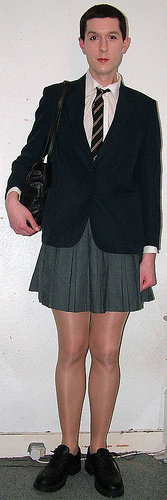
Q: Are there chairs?
A: No, there are no chairs.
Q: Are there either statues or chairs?
A: No, there are no chairs or statues.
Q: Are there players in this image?
A: No, there are no players.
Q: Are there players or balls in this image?
A: No, there are no players or balls.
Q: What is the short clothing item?
A: The clothing item is a skirt.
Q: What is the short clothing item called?
A: The clothing item is a skirt.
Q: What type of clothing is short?
A: The clothing is a skirt.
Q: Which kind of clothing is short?
A: The clothing is a skirt.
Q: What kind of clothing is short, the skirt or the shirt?
A: The skirt is short.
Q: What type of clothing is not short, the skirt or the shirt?
A: The shirt is not short.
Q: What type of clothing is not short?
A: The clothing is a shirt.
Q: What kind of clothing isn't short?
A: The clothing is a shirt.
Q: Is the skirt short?
A: Yes, the skirt is short.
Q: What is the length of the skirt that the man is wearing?
A: The skirt is short.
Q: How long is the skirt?
A: The skirt is short.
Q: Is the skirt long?
A: No, the skirt is short.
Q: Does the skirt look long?
A: No, the skirt is short.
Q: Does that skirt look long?
A: No, the skirt is short.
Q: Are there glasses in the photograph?
A: No, there are no glasses.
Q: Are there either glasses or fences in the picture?
A: No, there are no glasses or fences.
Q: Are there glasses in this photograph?
A: No, there are no glasses.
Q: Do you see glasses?
A: No, there are no glasses.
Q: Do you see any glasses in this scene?
A: No, there are no glasses.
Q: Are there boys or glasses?
A: No, there are no glasses or boys.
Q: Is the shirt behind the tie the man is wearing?
A: Yes, the shirt is behind the tie.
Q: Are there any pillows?
A: No, there are no pillows.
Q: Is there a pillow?
A: No, there are no pillows.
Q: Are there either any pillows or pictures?
A: No, there are no pillows or pictures.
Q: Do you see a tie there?
A: Yes, there is a tie.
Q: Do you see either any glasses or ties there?
A: Yes, there is a tie.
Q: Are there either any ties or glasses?
A: Yes, there is a tie.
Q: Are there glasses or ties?
A: Yes, there is a tie.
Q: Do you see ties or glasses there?
A: Yes, there is a tie.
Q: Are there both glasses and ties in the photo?
A: No, there is a tie but no glasses.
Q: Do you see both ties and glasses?
A: No, there is a tie but no glasses.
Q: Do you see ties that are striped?
A: Yes, there is a striped tie.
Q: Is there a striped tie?
A: Yes, there is a striped tie.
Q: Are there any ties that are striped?
A: Yes, there is a tie that is striped.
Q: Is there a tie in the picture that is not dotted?
A: Yes, there is a striped tie.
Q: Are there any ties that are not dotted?
A: Yes, there is a striped tie.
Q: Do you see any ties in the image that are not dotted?
A: Yes, there is a striped tie.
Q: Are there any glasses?
A: No, there are no glasses.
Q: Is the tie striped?
A: Yes, the tie is striped.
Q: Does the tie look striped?
A: Yes, the tie is striped.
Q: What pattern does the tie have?
A: The tie has striped pattern.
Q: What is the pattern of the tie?
A: The tie is striped.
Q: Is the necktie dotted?
A: No, the necktie is striped.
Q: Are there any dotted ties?
A: No, there is a tie but it is striped.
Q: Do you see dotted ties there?
A: No, there is a tie but it is striped.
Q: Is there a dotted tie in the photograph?
A: No, there is a tie but it is striped.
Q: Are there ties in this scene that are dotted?
A: No, there is a tie but it is striped.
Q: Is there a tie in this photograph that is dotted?
A: No, there is a tie but it is striped.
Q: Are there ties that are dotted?
A: No, there is a tie but it is striped.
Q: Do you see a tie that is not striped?
A: No, there is a tie but it is striped.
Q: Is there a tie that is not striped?
A: No, there is a tie but it is striped.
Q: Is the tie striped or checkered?
A: The tie is striped.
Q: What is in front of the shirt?
A: The tie is in front of the shirt.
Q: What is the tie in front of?
A: The tie is in front of the shirt.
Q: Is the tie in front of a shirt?
A: Yes, the tie is in front of a shirt.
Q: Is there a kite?
A: No, there are no kites.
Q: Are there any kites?
A: No, there are no kites.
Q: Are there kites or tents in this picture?
A: No, there are no kites or tents.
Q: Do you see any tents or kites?
A: No, there are no kites or tents.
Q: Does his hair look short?
A: Yes, the hair is short.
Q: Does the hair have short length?
A: Yes, the hair is short.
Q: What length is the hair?
A: The hair is short.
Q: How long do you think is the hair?
A: The hair is short.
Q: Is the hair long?
A: No, the hair is short.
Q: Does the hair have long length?
A: No, the hair is short.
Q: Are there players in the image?
A: No, there are no players.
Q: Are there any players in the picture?
A: No, there are no players.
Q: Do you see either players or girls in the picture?
A: No, there are no players or girls.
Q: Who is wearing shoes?
A: The man is wearing shoes.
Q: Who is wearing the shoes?
A: The man is wearing shoes.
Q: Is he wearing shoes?
A: Yes, the man is wearing shoes.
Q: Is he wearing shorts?
A: No, the man is wearing shoes.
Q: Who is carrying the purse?
A: The man is carrying the purse.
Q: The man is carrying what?
A: The man is carrying a purse.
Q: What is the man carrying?
A: The man is carrying a purse.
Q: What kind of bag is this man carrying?
A: The man is carrying a purse.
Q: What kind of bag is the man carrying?
A: The man is carrying a purse.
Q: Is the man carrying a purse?
A: Yes, the man is carrying a purse.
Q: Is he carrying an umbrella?
A: No, the man is carrying a purse.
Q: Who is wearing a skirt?
A: The man is wearing a skirt.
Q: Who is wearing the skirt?
A: The man is wearing a skirt.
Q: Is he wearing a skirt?
A: Yes, the man is wearing a skirt.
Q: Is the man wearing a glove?
A: No, the man is wearing a skirt.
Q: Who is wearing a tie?
A: The man is wearing a tie.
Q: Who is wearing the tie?
A: The man is wearing a tie.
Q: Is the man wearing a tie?
A: Yes, the man is wearing a tie.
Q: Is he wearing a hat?
A: No, the man is wearing a tie.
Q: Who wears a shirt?
A: The man wears a shirt.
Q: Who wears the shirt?
A: The man wears a shirt.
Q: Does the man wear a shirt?
A: Yes, the man wears a shirt.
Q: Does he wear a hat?
A: No, the man wears a shirt.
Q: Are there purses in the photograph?
A: Yes, there is a purse.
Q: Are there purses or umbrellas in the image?
A: Yes, there is a purse.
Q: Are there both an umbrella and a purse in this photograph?
A: No, there is a purse but no umbrellas.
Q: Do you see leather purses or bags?
A: Yes, there is a leather purse.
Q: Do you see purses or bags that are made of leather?
A: Yes, the purse is made of leather.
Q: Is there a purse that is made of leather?
A: Yes, there is a purse that is made of leather.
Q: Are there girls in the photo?
A: No, there are no girls.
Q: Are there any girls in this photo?
A: No, there are no girls.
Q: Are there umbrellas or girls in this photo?
A: No, there are no girls or umbrellas.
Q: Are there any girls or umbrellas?
A: No, there are no girls or umbrellas.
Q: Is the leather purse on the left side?
A: Yes, the purse is on the left of the image.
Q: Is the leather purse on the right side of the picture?
A: No, the purse is on the left of the image.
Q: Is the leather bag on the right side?
A: No, the purse is on the left of the image.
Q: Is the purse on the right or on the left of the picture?
A: The purse is on the left of the image.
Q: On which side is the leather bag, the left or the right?
A: The purse is on the left of the image.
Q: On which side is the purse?
A: The purse is on the left of the image.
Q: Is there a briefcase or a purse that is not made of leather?
A: No, there is a purse but it is made of leather.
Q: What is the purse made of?
A: The purse is made of leather.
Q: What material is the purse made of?
A: The purse is made of leather.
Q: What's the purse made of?
A: The purse is made of leather.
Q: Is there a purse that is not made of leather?
A: No, there is a purse but it is made of leather.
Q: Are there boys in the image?
A: No, there are no boys.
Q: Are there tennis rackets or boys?
A: No, there are no boys or tennis rackets.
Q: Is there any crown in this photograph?
A: No, there are no crowns.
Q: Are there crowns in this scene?
A: No, there are no crowns.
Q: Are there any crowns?
A: No, there are no crowns.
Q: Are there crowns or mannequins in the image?
A: No, there are no crowns or mannequins.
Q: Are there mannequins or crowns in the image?
A: No, there are no crowns or mannequins.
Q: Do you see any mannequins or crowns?
A: No, there are no crowns or mannequins.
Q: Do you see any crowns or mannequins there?
A: No, there are no crowns or mannequins.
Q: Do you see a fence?
A: No, there are no fences.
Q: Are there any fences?
A: No, there are no fences.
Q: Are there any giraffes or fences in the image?
A: No, there are no fences or giraffes.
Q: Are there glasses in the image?
A: No, there are no glasses.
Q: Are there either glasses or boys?
A: No, there are no glasses or boys.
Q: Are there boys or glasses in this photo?
A: No, there are no glasses or boys.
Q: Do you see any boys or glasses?
A: No, there are no glasses or boys.